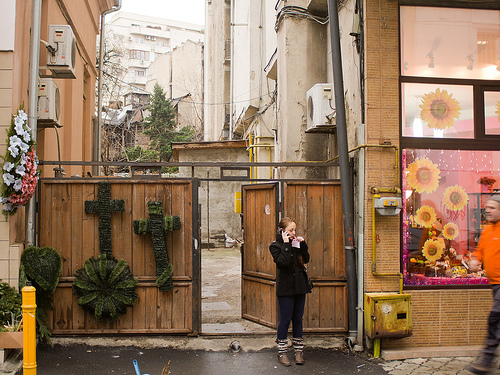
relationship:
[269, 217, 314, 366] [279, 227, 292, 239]
woman talking on cell phone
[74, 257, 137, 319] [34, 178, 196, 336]
wreath on wall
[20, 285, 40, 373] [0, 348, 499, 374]
pole in street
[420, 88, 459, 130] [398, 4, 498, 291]
sunflower in window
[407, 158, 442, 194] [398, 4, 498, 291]
sunflower in window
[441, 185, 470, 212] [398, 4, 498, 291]
sunflower in window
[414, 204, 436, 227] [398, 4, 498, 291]
sunflower in window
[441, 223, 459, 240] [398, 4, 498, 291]
sunflower in window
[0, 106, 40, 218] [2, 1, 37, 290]
flower hanging on wall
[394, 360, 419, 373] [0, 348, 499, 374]
brick on street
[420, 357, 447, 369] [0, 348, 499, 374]
brick on street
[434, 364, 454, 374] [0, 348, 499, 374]
brick on street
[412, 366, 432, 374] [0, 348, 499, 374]
brick on street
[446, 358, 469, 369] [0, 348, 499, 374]
brick on street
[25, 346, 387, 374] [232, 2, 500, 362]
pavement near building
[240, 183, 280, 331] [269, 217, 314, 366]
gate behind woman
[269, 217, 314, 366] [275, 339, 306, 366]
woman wearing boots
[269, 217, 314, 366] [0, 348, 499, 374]
woman on street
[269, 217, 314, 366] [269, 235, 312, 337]
woman wearing clothes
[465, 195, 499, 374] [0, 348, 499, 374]
man walking on street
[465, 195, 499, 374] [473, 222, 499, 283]
man wearing sweatshirt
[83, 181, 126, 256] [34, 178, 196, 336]
cross on wall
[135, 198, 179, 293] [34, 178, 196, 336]
cross on wall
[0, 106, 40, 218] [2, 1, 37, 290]
flowers on wall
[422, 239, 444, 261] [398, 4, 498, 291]
sunflower on window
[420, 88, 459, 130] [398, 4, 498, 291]
sunflower on window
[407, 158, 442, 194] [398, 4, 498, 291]
sunflower on window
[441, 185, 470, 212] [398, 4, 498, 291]
sunflower on window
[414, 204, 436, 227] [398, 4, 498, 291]
sunflower on window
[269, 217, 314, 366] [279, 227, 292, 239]
woman speaking through cell phone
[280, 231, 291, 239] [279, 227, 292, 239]
hand holding cell phone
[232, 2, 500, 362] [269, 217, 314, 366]
building behind woman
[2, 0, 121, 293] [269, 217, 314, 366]
building behind woman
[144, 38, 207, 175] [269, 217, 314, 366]
building behind woman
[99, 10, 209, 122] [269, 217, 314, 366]
building behind woman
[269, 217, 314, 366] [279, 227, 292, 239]
woman holding cell phone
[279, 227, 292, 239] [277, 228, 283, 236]
cell phone next to ear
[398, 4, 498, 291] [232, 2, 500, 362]
window on building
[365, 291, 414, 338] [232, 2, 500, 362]
gas meter on building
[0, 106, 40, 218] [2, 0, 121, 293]
flowers on building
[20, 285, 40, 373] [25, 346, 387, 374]
pole on pavement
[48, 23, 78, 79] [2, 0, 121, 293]
air conditioner on building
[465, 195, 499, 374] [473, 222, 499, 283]
man in sweatshirt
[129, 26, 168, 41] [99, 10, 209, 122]
balcony on building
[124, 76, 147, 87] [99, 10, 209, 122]
balcony on building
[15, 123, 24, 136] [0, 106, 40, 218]
flower in bouquet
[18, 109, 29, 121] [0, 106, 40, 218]
flower in bouquet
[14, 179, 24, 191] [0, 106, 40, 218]
flower in bouquet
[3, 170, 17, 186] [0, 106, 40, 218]
flower in bouquet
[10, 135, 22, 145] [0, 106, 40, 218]
flower in bouquet